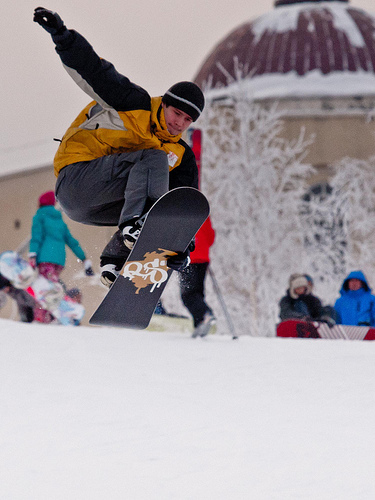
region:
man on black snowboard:
[30, 5, 209, 331]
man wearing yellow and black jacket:
[28, 3, 198, 283]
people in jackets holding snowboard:
[278, 268, 372, 343]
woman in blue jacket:
[0, 189, 94, 325]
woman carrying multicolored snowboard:
[0, 190, 95, 320]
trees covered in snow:
[192, 55, 372, 335]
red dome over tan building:
[0, 0, 373, 328]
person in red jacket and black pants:
[177, 209, 217, 337]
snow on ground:
[0, 319, 373, 498]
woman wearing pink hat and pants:
[4, 190, 93, 327]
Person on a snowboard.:
[30, 2, 245, 325]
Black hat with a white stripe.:
[157, 71, 204, 146]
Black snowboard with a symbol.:
[81, 180, 213, 337]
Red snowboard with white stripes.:
[270, 315, 370, 347]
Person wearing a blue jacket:
[326, 267, 373, 326]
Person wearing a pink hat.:
[29, 184, 67, 209]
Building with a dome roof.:
[186, 1, 374, 141]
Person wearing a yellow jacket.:
[27, 2, 228, 292]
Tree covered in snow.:
[159, 52, 373, 340]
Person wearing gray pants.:
[29, 5, 207, 292]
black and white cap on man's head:
[162, 79, 206, 139]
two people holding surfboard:
[285, 274, 373, 343]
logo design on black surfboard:
[126, 235, 172, 284]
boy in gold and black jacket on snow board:
[30, 10, 155, 325]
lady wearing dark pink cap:
[26, 187, 57, 203]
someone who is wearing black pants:
[180, 262, 210, 314]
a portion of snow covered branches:
[225, 99, 367, 252]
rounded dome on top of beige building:
[189, 0, 369, 75]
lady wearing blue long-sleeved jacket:
[34, 208, 85, 263]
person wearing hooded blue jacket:
[328, 270, 373, 318]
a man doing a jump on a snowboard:
[21, 3, 230, 321]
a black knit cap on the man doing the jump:
[158, 80, 207, 115]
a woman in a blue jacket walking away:
[27, 188, 80, 278]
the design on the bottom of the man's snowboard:
[127, 243, 179, 296]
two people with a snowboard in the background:
[275, 267, 372, 338]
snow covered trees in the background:
[227, 120, 368, 233]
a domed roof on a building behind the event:
[161, 10, 372, 96]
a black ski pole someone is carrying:
[197, 254, 251, 344]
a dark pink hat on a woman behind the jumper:
[34, 186, 61, 209]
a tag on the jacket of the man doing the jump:
[163, 149, 183, 171]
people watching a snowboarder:
[268, 251, 374, 331]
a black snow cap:
[165, 69, 214, 120]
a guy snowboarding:
[36, 27, 217, 329]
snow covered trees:
[170, 55, 374, 332]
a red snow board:
[274, 310, 374, 345]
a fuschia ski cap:
[36, 186, 60, 205]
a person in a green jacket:
[29, 189, 91, 326]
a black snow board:
[90, 178, 204, 337]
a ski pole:
[203, 253, 258, 354]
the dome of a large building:
[180, 5, 373, 113]